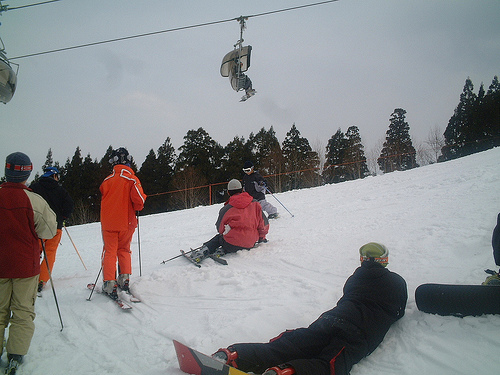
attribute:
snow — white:
[10, 141, 499, 374]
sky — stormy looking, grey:
[0, 1, 498, 171]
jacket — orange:
[97, 163, 148, 233]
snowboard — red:
[171, 339, 249, 374]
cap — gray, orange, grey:
[4, 150, 35, 183]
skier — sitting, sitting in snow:
[180, 176, 279, 268]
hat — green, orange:
[356, 239, 391, 268]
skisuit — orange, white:
[93, 163, 147, 284]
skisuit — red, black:
[201, 193, 274, 259]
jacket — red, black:
[212, 190, 274, 247]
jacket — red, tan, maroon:
[0, 178, 61, 282]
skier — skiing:
[236, 160, 282, 225]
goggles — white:
[238, 167, 255, 175]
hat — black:
[237, 160, 254, 170]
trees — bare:
[412, 124, 447, 168]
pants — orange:
[98, 227, 139, 284]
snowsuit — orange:
[94, 162, 148, 280]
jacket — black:
[307, 259, 408, 345]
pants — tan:
[1, 273, 41, 356]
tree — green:
[377, 103, 421, 174]